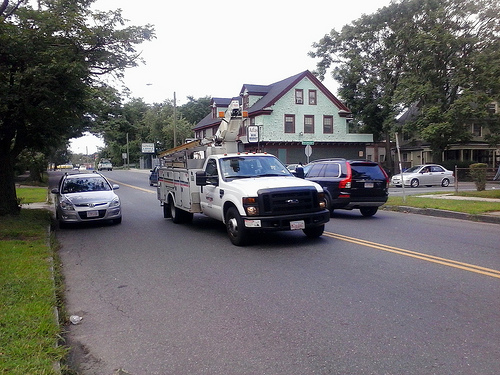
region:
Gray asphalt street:
[118, 279, 320, 334]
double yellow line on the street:
[393, 235, 460, 274]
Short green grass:
[22, 248, 52, 358]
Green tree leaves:
[30, 27, 85, 102]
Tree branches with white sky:
[101, 6, 203, 71]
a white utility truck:
[152, 142, 336, 244]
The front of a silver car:
[48, 169, 130, 233]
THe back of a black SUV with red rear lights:
[329, 152, 395, 218]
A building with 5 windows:
[240, 65, 375, 141]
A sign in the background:
[135, 135, 159, 157]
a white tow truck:
[174, 132, 328, 272]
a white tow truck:
[153, 85, 284, 335]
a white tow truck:
[191, 124, 347, 372]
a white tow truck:
[224, 45, 405, 329]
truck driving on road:
[145, 150, 332, 246]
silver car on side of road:
[46, 161, 131, 249]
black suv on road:
[316, 156, 385, 223]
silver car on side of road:
[385, 157, 452, 188]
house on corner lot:
[228, 68, 370, 155]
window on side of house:
[291, 87, 303, 106]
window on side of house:
[306, 87, 320, 105]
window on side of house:
[276, 108, 296, 135]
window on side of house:
[303, 114, 318, 136]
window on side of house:
[321, 109, 336, 134]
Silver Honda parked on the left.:
[54, 173, 126, 225]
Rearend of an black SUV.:
[339, 159, 391, 214]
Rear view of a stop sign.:
[305, 146, 312, 156]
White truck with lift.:
[142, 99, 330, 244]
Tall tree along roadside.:
[6, 3, 156, 210]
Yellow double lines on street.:
[338, 229, 497, 293]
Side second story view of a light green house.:
[255, 66, 374, 142]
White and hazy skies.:
[175, 19, 297, 66]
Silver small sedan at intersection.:
[394, 163, 455, 187]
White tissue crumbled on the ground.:
[71, 314, 82, 324]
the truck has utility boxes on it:
[148, 127, 338, 276]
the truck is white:
[131, 130, 338, 261]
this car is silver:
[49, 167, 139, 239]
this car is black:
[290, 150, 411, 220]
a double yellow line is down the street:
[334, 230, 483, 300]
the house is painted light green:
[239, 73, 368, 150]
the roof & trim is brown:
[246, 77, 351, 129]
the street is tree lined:
[0, 46, 142, 354]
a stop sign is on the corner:
[288, 132, 329, 165]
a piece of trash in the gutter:
[68, 307, 94, 337]